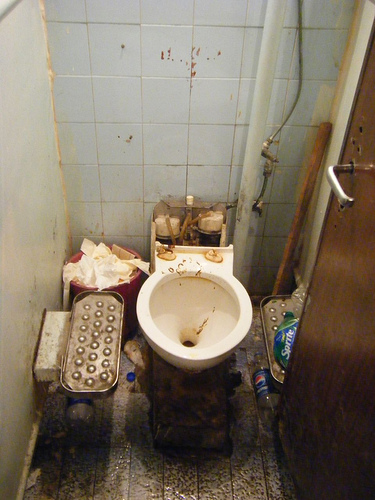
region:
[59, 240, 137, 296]
the trash can is full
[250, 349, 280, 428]
empty soda bottle on the ground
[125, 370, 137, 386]
bottle cap is blue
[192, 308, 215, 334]
stains on the toilet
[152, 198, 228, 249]
toilet plumbing is exposed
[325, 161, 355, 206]
a silver door handle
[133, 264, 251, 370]
the toilet has no water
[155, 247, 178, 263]
rust stains on the toilet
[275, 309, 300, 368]
a green soda bottle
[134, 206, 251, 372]
A very rusty nasty white half a toilet.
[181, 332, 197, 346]
Dark hole in a toilet bowl.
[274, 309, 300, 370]
Empty green sprite bottle.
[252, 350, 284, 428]
The most visible pepsi bottle with no lid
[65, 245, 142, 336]
A red trashcan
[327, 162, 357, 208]
A silver door lever.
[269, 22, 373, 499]
A brown door with silver handle.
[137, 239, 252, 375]
The bottom half of a white toilet.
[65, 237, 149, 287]
White trash coming out of a trashcan.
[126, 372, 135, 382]
A blue cap on the floor.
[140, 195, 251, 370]
dirty rusty broken toilet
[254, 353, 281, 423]
empty clear pepsi bottle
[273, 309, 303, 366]
green empty sprite bottle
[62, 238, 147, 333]
over flowing red garbage can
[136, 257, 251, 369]
dirty white toilet bowl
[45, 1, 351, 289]
dirty tiled wall with moldy grout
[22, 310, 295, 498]
dirty grey floor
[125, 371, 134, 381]
blue pop cap on floor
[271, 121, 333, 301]
dirty piece of wood in corner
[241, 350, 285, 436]
clear plastic soda bottle on ground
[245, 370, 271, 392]
company logo on soda bottle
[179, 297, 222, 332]
stains on toilet bowl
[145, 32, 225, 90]
rust stains on white bathroom tile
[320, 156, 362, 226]
silver metal door handle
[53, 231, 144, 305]
full red trashcan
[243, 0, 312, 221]
brass plumbing lines hanging on wall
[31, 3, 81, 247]
caulk line in corner of bathroom wall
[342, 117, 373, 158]
holes in wooden bathroom door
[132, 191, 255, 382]
a toilet is dirty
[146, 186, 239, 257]
a tank is broken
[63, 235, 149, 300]
a trash can is full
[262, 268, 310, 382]
an empty bottle of soda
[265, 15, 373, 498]
the door is brown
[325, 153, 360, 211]
a handle color silver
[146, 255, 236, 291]
brown stains on toilet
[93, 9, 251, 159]
brown spots on wall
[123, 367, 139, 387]
a blue cup on the floor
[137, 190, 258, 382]
a broken white toilet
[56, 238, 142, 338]
a full red trash can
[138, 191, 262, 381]
a dirty toilet attached to a wall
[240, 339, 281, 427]
an empty pepsi bottle on the floor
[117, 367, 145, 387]
a blue bottle top on the ground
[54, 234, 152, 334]
a trashcan filled with paper trash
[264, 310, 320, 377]
an empty sprite bottle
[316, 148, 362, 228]
a silver handle on a door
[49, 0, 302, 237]
a tile wall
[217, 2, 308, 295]
a white pipe against the wall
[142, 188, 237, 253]
exposed inside of a toilet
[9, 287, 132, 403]
stand attached to a wall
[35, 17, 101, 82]
old and dirty wall tile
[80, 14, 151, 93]
old and dirty wall tile